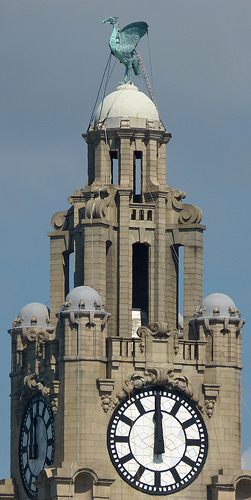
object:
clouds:
[21, 9, 61, 55]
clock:
[107, 382, 210, 491]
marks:
[173, 406, 177, 413]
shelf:
[203, 382, 220, 418]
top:
[93, 77, 163, 134]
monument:
[101, 14, 151, 83]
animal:
[101, 13, 148, 85]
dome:
[91, 81, 162, 123]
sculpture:
[101, 16, 151, 83]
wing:
[120, 20, 149, 53]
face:
[106, 389, 210, 495]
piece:
[107, 43, 118, 58]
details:
[136, 322, 181, 382]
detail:
[59, 285, 110, 320]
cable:
[133, 154, 205, 316]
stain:
[75, 325, 82, 464]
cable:
[84, 50, 110, 132]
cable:
[97, 52, 111, 126]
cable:
[145, 29, 154, 101]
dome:
[10, 302, 50, 326]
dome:
[65, 285, 104, 312]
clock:
[17, 393, 54, 499]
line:
[170, 400, 181, 415]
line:
[182, 416, 197, 428]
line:
[186, 438, 201, 445]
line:
[181, 453, 196, 466]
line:
[169, 465, 180, 482]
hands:
[153, 389, 165, 455]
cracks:
[136, 431, 149, 461]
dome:
[194, 292, 241, 323]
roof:
[189, 292, 247, 328]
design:
[112, 363, 205, 416]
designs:
[93, 299, 108, 314]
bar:
[169, 401, 181, 416]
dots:
[162, 483, 166, 493]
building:
[0, 14, 249, 500]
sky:
[0, 0, 251, 482]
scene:
[0, 0, 248, 499]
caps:
[14, 298, 51, 332]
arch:
[72, 465, 95, 498]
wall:
[59, 378, 108, 487]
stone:
[87, 448, 107, 467]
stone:
[92, 460, 112, 477]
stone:
[214, 439, 233, 451]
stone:
[209, 449, 231, 464]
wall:
[207, 420, 233, 487]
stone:
[206, 456, 225, 468]